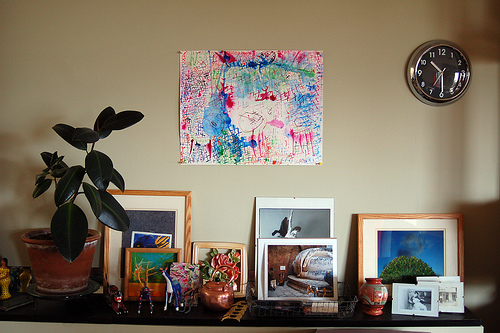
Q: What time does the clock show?
A: 10:30.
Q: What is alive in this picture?
A: The plant.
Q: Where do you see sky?
A: In a photo.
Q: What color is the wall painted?
A: Tan.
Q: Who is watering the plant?
A: No one.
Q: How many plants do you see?
A: 1.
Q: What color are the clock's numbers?
A: White.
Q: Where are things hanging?
A: On the wall.